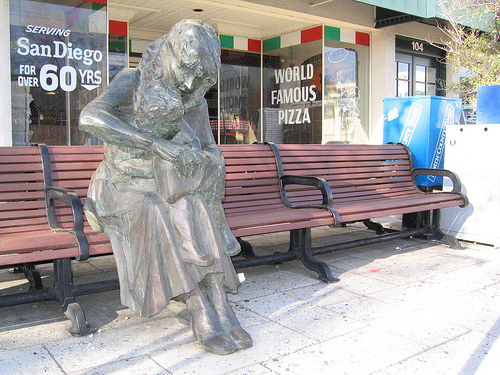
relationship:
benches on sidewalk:
[2, 145, 452, 256] [1, 213, 498, 373]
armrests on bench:
[409, 164, 464, 195] [0, 136, 471, 307]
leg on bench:
[53, 260, 92, 334] [0, 142, 467, 336]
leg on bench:
[291, 229, 336, 284] [0, 142, 467, 336]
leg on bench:
[428, 211, 462, 248] [0, 142, 467, 336]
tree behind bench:
[424, 0, 492, 122] [0, 142, 467, 336]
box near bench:
[429, 121, 498, 238] [267, 132, 479, 278]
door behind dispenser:
[327, 40, 408, 101] [371, 99, 496, 206]